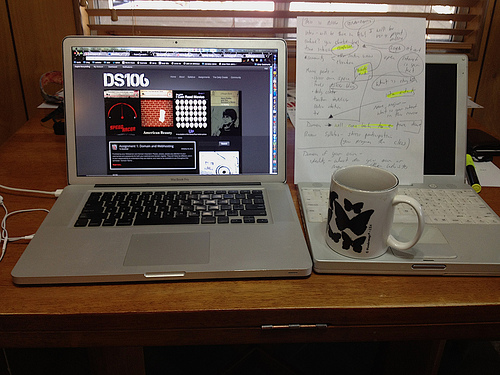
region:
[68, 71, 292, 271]
the laptop is on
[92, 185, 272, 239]
the keys are black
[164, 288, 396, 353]
the surface is wooden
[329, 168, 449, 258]
he cup is white and black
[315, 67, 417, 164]
the paper has drawings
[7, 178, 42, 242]
the cables are white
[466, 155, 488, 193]
the marker pen is black and yellow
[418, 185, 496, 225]
the keys are white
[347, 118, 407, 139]
the writing is highlighted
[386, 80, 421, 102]
the writing is highlighted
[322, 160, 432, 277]
a white cup on a desk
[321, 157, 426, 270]
cup has black butterflies designs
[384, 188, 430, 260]
handle of cup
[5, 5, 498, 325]
two laptops on desk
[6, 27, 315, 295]
a laptop on a desk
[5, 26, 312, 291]
laptop is color silver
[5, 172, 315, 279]
black keys on a gray laptop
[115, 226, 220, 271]
touchpad in front of keyboard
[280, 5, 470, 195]
a paper covering the screen of laptop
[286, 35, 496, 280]
a silver laptop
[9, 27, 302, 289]
a lap top open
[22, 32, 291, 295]
a lap top turned on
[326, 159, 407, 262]
a black and white cup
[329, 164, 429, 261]
a cup sitting a computer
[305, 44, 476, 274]
a lap top open not turned on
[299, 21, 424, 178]
a white piece of paper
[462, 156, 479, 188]
a green and black marker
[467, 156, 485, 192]
a green and black highlighter marker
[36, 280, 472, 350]
a brown wooden table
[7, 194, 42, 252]
cable to a computer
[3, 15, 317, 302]
silver laptop on desk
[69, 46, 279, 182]
webpage open on laptop computer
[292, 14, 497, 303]
laptop powered off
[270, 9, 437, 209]
paper with notes propped on laptop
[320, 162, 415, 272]
coffee cup on laptop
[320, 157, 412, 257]
coffee cup with black butterflies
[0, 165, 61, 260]
cords for devices on laptop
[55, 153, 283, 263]
black keys on laptop keyboard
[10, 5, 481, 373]
2 laptops sitting on wood desk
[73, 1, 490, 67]
brown slats on blinds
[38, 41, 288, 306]
a silver laptop on a desk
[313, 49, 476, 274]
a laptop with a piece of paper on it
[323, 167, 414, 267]
a black and white coffee cup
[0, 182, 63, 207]
a white cord attached to a laptop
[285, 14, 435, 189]
a piece of paper with writing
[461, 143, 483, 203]
a yellow majic marker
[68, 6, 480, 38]
a window covered with a mini blind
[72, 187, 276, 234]
black keys on a laptop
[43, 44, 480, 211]
two laptops on a desk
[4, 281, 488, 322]
a wood desk